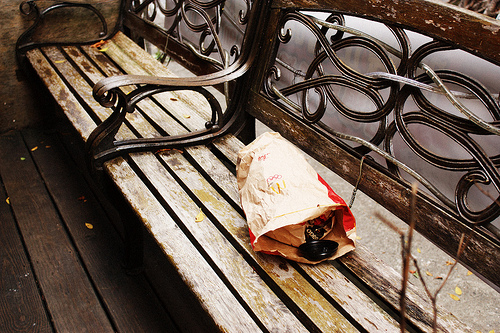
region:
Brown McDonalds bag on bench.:
[232, 131, 359, 264]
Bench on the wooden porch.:
[23, 5, 498, 327]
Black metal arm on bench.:
[90, 58, 255, 160]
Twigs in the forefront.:
[377, 174, 455, 331]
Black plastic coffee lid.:
[295, 235, 340, 259]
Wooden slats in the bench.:
[23, 42, 494, 326]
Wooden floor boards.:
[2, 117, 189, 329]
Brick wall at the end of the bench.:
[3, 1, 103, 118]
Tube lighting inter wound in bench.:
[348, 64, 494, 134]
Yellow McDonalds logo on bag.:
[266, 178, 287, 197]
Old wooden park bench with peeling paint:
[11, 1, 496, 327]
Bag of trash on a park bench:
[235, 130, 360, 265]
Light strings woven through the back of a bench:
[250, 0, 494, 176]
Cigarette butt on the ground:
[27, 143, 52, 156]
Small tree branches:
[373, 181, 470, 329]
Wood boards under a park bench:
[0, 102, 195, 325]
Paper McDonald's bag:
[234, 129, 359, 268]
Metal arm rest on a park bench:
[75, 63, 258, 165]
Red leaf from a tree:
[88, 37, 115, 58]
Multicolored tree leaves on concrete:
[397, 242, 480, 312]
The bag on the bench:
[222, 120, 362, 266]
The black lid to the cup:
[296, 236, 340, 264]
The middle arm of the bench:
[84, 2, 272, 162]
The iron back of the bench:
[121, 0, 498, 265]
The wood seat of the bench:
[27, 30, 459, 331]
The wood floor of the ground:
[0, 122, 205, 331]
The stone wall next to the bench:
[0, 0, 130, 130]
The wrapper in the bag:
[269, 209, 336, 246]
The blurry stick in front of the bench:
[369, 176, 461, 330]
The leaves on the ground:
[2, 138, 109, 235]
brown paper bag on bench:
[211, 133, 363, 270]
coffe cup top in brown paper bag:
[276, 232, 351, 262]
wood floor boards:
[6, 131, 188, 331]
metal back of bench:
[271, 5, 496, 229]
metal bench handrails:
[87, 59, 249, 165]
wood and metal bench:
[9, 0, 498, 327]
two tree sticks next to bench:
[369, 170, 465, 331]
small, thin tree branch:
[431, 229, 469, 296]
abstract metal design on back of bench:
[288, 13, 495, 215]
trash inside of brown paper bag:
[267, 220, 343, 240]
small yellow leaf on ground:
[76, 212, 109, 239]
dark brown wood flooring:
[31, 223, 92, 308]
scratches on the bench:
[415, 11, 467, 34]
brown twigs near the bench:
[386, 173, 431, 279]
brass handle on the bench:
[84, 60, 239, 147]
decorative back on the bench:
[290, 37, 465, 134]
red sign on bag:
[311, 165, 354, 205]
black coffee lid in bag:
[293, 230, 354, 260]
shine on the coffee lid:
[310, 248, 335, 258]